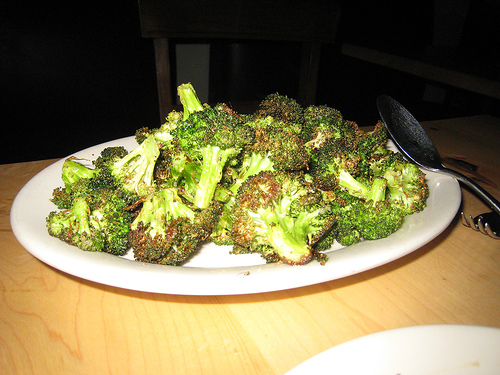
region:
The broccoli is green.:
[52, 75, 430, 272]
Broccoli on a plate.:
[55, 69, 418, 250]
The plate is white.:
[18, 103, 457, 283]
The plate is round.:
[17, 92, 477, 294]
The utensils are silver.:
[372, 85, 498, 240]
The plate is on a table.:
[5, 105, 476, 372]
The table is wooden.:
[5, 136, 497, 337]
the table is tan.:
[5, 137, 489, 367]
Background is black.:
[10, 7, 490, 172]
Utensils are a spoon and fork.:
[376, 87, 498, 239]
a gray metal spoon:
[374, 94, 499, 224]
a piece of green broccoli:
[229, 167, 335, 269]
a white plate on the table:
[6, 117, 462, 300]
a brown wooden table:
[1, 107, 498, 374]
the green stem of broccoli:
[190, 148, 228, 209]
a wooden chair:
[136, 5, 340, 124]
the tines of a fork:
[455, 204, 498, 241]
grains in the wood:
[100, 286, 248, 373]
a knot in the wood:
[442, 147, 497, 185]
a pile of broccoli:
[39, 77, 433, 265]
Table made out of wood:
[348, 297, 411, 320]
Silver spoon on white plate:
[372, 85, 497, 170]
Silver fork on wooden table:
[461, 207, 498, 250]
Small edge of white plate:
[191, 267, 244, 293]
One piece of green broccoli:
[173, 113, 254, 200]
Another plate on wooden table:
[387, 335, 454, 369]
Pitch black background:
[6, 25, 78, 77]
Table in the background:
[345, 35, 495, 95]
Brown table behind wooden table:
[135, 5, 172, 45]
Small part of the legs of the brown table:
[147, 45, 173, 90]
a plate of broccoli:
[67, 82, 433, 264]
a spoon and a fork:
[365, 85, 496, 235]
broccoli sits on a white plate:
[7, 105, 477, 295]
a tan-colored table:
[0, 107, 496, 370]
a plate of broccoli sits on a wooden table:
[0, 107, 497, 374]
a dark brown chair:
[117, 0, 332, 120]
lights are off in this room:
[0, 4, 497, 119]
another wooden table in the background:
[335, 9, 495, 113]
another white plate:
[277, 319, 496, 373]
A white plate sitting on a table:
[2, 2, 494, 372]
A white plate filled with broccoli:
[5, 70, 490, 295]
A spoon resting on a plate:
[351, 80, 496, 240]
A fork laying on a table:
[455, 165, 495, 255]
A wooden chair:
[135, 5, 330, 120]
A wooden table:
[5, 240, 195, 370]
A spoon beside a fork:
[375, 90, 495, 235]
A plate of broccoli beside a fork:
[10, 90, 491, 297]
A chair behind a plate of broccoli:
[52, 4, 446, 281]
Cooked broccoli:
[58, 86, 425, 247]